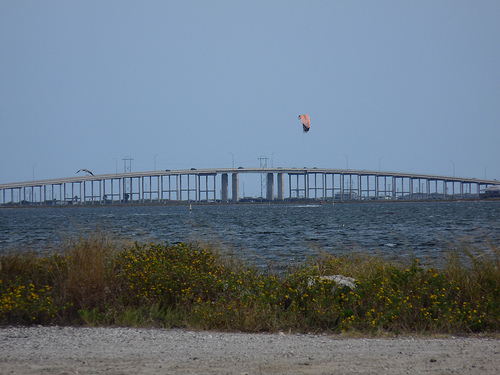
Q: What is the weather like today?
A: It is clear.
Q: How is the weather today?
A: It is clear.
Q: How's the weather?
A: It is clear.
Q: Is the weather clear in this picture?
A: Yes, it is clear.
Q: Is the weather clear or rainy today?
A: It is clear.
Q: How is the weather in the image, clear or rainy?
A: It is clear.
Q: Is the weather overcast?
A: No, it is clear.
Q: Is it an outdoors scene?
A: Yes, it is outdoors.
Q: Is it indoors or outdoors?
A: It is outdoors.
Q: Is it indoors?
A: No, it is outdoors.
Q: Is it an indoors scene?
A: No, it is outdoors.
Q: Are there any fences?
A: No, there are no fences.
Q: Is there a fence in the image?
A: No, there are no fences.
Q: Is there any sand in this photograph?
A: Yes, there is sand.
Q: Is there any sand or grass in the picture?
A: Yes, there is sand.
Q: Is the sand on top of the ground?
A: Yes, the sand is on top of the ground.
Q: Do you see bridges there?
A: Yes, there is a bridge.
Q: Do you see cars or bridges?
A: Yes, there is a bridge.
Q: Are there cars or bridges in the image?
A: Yes, there is a bridge.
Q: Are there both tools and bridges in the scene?
A: No, there is a bridge but no tools.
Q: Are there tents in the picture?
A: No, there are no tents.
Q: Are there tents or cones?
A: No, there are no tents or cones.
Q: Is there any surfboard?
A: No, there are no surfboards.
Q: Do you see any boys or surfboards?
A: No, there are no surfboards or boys.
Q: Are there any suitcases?
A: No, there are no suitcases.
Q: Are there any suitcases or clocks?
A: No, there are no suitcases or clocks.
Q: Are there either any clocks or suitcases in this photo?
A: No, there are no suitcases or clocks.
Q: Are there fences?
A: No, there are no fences.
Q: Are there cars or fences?
A: No, there are no fences or cars.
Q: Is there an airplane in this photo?
A: No, there are no airplanes.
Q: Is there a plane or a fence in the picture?
A: No, there are no airplanes or fences.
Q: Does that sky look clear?
A: Yes, the sky is clear.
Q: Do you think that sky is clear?
A: Yes, the sky is clear.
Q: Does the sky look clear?
A: Yes, the sky is clear.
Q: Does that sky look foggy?
A: No, the sky is clear.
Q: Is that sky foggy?
A: No, the sky is clear.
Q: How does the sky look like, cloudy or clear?
A: The sky is clear.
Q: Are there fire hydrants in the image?
A: No, there are no fire hydrants.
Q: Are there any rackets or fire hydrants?
A: No, there are no fire hydrants or rackets.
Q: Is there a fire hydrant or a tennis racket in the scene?
A: No, there are no fire hydrants or rackets.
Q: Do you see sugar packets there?
A: No, there are no sugar packets.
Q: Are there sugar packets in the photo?
A: No, there are no sugar packets.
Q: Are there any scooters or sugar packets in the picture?
A: No, there are no sugar packets or scooters.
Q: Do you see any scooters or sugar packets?
A: No, there are no sugar packets or scooters.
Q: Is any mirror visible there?
A: No, there are no mirrors.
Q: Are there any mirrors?
A: No, there are no mirrors.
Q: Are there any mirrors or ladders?
A: No, there are no mirrors or ladders.